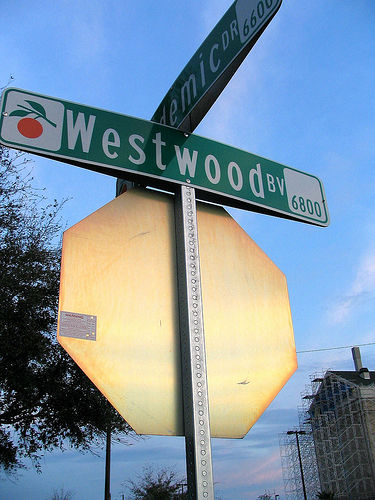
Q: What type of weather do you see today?
A: It is clear.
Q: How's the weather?
A: It is clear.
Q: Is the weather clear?
A: Yes, it is clear.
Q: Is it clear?
A: Yes, it is clear.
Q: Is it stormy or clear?
A: It is clear.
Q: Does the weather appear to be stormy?
A: No, it is clear.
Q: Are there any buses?
A: No, there are no buses.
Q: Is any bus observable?
A: No, there are no buses.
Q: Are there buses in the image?
A: No, there are no buses.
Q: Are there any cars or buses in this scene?
A: No, there are no buses or cars.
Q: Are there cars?
A: No, there are no cars.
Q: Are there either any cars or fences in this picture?
A: No, there are no cars or fences.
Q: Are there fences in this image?
A: No, there are no fences.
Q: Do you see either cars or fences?
A: No, there are no fences or cars.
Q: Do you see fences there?
A: No, there are no fences.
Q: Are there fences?
A: No, there are no fences.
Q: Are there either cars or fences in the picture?
A: No, there are no fences or cars.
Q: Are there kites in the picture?
A: No, there are no kites.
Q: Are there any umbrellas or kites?
A: No, there are no kites or umbrellas.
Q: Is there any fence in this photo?
A: No, there are no fences.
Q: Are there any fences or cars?
A: No, there are no fences or cars.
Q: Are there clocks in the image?
A: No, there are no clocks.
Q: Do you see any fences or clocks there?
A: No, there are no clocks or fences.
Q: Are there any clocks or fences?
A: No, there are no clocks or fences.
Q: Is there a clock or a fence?
A: No, there are no clocks or fences.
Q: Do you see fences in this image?
A: No, there are no fences.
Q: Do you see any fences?
A: No, there are no fences.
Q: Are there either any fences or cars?
A: No, there are no fences or cars.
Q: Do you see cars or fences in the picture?
A: No, there are no fences or cars.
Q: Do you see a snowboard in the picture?
A: No, there are no snowboards.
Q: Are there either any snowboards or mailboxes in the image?
A: No, there are no snowboards or mailboxes.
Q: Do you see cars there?
A: No, there are no cars.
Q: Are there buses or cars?
A: No, there are no cars or buses.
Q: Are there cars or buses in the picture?
A: No, there are no cars or buses.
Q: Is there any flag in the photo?
A: No, there are no flags.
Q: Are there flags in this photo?
A: No, there are no flags.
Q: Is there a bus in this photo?
A: No, there are no buses.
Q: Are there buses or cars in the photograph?
A: No, there are no buses or cars.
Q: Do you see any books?
A: No, there are no books.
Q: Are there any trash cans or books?
A: No, there are no books or trash cans.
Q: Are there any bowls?
A: No, there are no bowls.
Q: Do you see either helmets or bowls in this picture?
A: No, there are no bowls or helmets.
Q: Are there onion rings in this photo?
A: No, there are no onion rings.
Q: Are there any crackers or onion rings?
A: No, there are no onion rings or crackers.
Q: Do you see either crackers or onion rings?
A: No, there are no onion rings or crackers.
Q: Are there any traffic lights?
A: No, there are no traffic lights.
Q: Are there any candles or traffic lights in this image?
A: No, there are no traffic lights or candles.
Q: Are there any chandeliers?
A: No, there are no chandeliers.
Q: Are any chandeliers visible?
A: No, there are no chandeliers.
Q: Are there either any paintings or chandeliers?
A: No, there are no chandeliers or paintings.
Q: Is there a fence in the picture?
A: No, there are no fences.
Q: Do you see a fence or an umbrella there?
A: No, there are no fences or umbrellas.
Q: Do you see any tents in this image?
A: No, there are no tents.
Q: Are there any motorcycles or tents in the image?
A: No, there are no tents or motorcycles.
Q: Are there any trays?
A: No, there are no trays.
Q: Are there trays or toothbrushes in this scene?
A: No, there are no trays or toothbrushes.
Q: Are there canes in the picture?
A: No, there are no canes.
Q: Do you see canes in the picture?
A: No, there are no canes.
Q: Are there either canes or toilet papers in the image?
A: No, there are no canes or toilet papers.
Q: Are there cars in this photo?
A: No, there are no cars.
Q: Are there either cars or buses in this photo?
A: No, there are no cars or buses.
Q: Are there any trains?
A: No, there are no trains.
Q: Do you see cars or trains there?
A: No, there are no trains or cars.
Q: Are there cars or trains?
A: No, there are no trains or cars.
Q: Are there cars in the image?
A: No, there are no cars.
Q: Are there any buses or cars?
A: No, there are no cars or buses.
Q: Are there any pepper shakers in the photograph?
A: No, there are no pepper shakers.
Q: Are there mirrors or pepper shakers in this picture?
A: No, there are no pepper shakers or mirrors.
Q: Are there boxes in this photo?
A: No, there are no boxes.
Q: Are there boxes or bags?
A: No, there are no boxes or bags.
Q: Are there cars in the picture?
A: No, there are no cars.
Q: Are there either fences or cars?
A: No, there are no cars or fences.